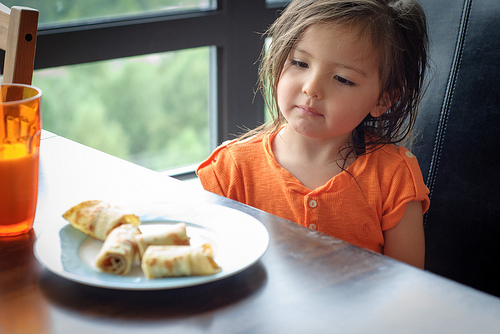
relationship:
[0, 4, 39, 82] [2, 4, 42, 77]
chair see back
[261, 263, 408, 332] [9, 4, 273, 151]
light from window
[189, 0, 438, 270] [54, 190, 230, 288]
girl eat food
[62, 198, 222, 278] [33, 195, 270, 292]
food on plate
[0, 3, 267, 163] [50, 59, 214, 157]
window shows trees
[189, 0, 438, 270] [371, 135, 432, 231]
girl wears shirt sleeves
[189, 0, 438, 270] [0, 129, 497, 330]
girl at table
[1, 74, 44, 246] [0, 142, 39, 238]
cup has drink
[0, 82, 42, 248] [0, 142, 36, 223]
cup has milk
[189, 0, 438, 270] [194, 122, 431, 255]
girl wearing shirt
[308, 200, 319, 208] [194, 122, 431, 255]
button on shirt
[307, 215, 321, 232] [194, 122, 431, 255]
button on shirt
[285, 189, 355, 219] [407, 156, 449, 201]
button on strap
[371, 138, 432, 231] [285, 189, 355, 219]
shirt sleeves has button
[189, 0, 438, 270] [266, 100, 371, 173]
girl has neck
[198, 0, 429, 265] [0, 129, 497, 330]
girl sitting at table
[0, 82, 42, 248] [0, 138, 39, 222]
cup has milk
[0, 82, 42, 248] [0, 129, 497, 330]
cup on table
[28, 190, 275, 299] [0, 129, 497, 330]
plate on table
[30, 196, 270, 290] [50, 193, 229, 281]
plate has food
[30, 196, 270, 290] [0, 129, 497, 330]
plate on table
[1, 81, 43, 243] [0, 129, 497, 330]
drink on table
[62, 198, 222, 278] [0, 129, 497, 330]
food on table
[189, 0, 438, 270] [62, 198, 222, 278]
girl looking at food